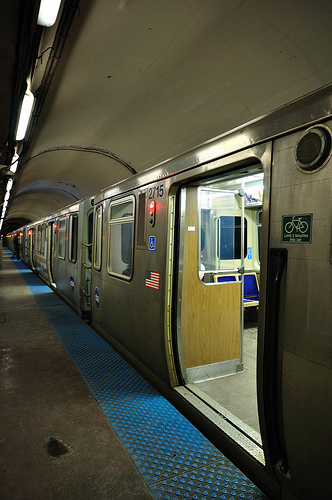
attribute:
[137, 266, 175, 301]
flag sticker — american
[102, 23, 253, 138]
cieling — concrete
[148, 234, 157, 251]
sign — white, blue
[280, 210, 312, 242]
sign — white, green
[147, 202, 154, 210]
light — red, lit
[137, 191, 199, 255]
light — red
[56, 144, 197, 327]
train — silver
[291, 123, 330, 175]
speaker — round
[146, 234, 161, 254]
sign — handicapped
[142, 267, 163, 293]
flag — american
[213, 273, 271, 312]
seat — blue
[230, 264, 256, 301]
seat — blue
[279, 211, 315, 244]
sign — green, white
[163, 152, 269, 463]
doors — open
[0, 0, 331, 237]
ceiling — white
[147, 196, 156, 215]
light — red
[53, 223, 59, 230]
light — red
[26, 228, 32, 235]
light — red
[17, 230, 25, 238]
light — red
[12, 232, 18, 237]
light — red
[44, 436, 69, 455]
puddle — small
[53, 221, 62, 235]
light — red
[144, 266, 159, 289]
flag — American